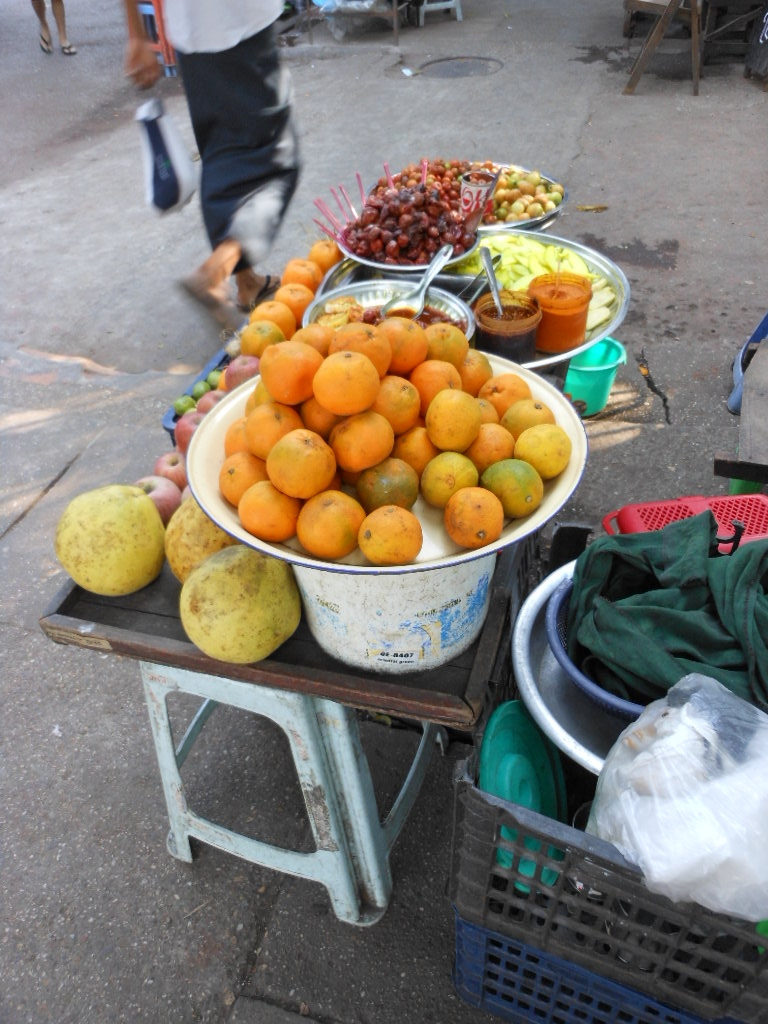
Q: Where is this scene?
A: On the street.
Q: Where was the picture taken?
A: Street market.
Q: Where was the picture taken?
A: At a market.